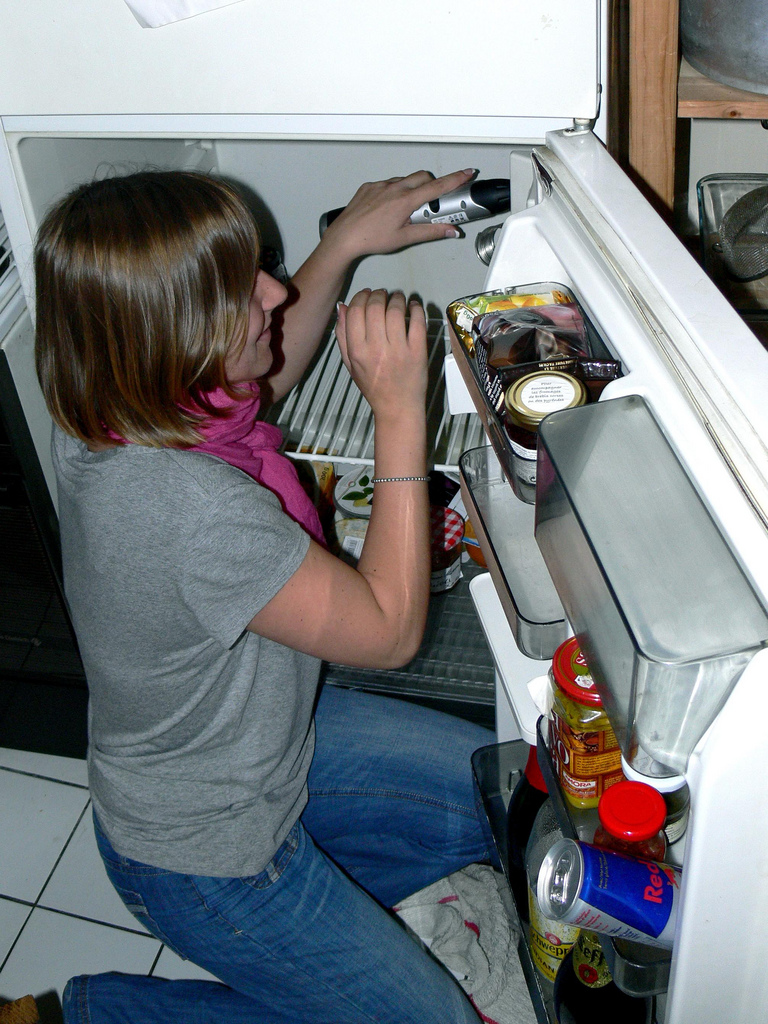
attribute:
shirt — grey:
[32, 416, 351, 876]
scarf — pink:
[96, 364, 328, 557]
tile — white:
[5, 747, 222, 993]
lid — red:
[597, 783, 666, 838]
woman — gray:
[24, 155, 637, 1022]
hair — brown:
[34, 162, 256, 451]